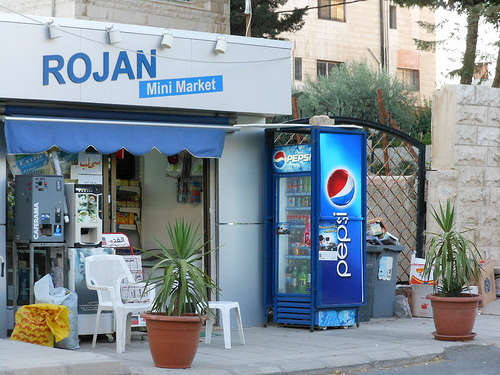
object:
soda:
[287, 177, 311, 193]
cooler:
[272, 122, 370, 330]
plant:
[150, 215, 222, 316]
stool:
[82, 251, 156, 352]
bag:
[8, 301, 69, 350]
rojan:
[38, 48, 158, 86]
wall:
[430, 84, 498, 267]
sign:
[139, 73, 222, 101]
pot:
[141, 311, 205, 369]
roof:
[150, 19, 284, 40]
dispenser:
[74, 224, 103, 249]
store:
[24, 152, 215, 306]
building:
[5, 1, 500, 330]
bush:
[324, 82, 357, 104]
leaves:
[426, 359, 441, 367]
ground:
[206, 312, 491, 375]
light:
[214, 34, 231, 54]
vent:
[274, 307, 315, 330]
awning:
[7, 103, 228, 160]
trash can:
[366, 246, 402, 317]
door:
[273, 116, 427, 281]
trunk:
[378, 161, 402, 176]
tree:
[301, 58, 420, 137]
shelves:
[0, 101, 242, 135]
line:
[272, 0, 364, 13]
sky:
[451, 17, 464, 23]